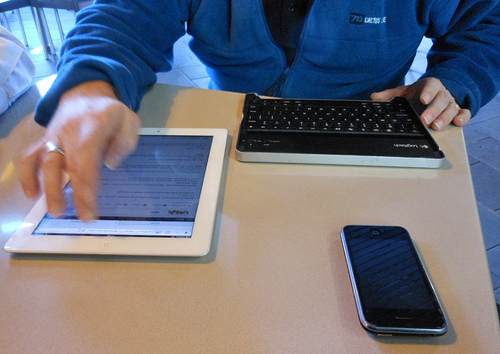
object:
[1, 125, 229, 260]
ipad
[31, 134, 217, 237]
browser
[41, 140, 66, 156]
ring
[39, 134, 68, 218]
finger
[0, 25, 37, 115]
bag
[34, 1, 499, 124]
blue jacket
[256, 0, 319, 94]
zipper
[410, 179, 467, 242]
wood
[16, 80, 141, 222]
hand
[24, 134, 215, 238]
screen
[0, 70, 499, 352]
table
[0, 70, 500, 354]
desk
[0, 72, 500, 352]
table top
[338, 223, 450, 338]
cellphone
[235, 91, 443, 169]
keyboard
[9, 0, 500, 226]
man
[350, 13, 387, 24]
logo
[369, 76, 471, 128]
hand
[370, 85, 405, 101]
thumb